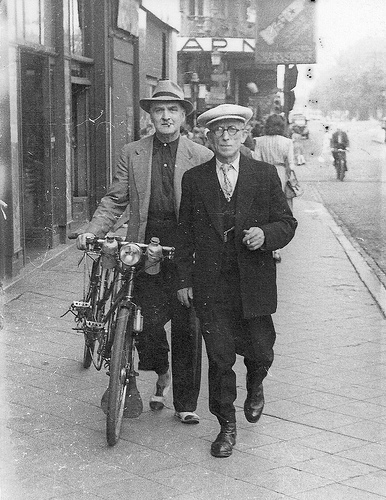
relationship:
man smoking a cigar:
[76, 80, 214, 425] [166, 121, 173, 127]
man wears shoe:
[110, 72, 204, 442] [173, 407, 201, 426]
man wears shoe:
[110, 72, 204, 442] [151, 376, 170, 411]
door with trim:
[15, 46, 53, 264] [15, 42, 57, 270]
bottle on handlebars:
[144, 237, 163, 276] [82, 234, 178, 274]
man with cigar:
[135, 78, 201, 166] [166, 121, 170, 129]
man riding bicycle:
[329, 125, 348, 170] [331, 147, 349, 180]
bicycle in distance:
[331, 147, 349, 180] [0, 15, 373, 290]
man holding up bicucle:
[76, 65, 223, 426] [52, 222, 168, 437]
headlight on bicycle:
[119, 240, 142, 267] [58, 228, 177, 449]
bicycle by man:
[58, 228, 177, 449] [173, 102, 295, 455]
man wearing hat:
[173, 102, 295, 455] [193, 103, 253, 123]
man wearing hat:
[76, 80, 214, 425] [138, 81, 194, 111]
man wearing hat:
[86, 108, 192, 433] [137, 76, 195, 108]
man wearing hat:
[193, 119, 312, 462] [194, 103, 263, 131]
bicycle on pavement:
[58, 228, 177, 449] [0, 194, 384, 495]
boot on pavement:
[212, 413, 237, 457] [25, 182, 379, 497]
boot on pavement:
[246, 373, 267, 417] [25, 182, 379, 497]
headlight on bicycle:
[119, 243, 143, 268] [69, 229, 182, 446]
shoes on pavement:
[176, 409, 199, 422] [0, 194, 384, 495]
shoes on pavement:
[150, 374, 170, 410] [0, 194, 384, 495]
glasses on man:
[198, 120, 250, 143] [173, 102, 295, 455]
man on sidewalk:
[173, 102, 295, 455] [0, 196, 386, 499]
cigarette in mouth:
[164, 121, 172, 125] [158, 120, 174, 127]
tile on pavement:
[331, 380, 383, 404] [294, 336, 380, 493]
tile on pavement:
[290, 450, 382, 483] [294, 336, 380, 493]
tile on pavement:
[316, 353, 384, 375] [294, 336, 380, 493]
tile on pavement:
[291, 387, 356, 411] [294, 336, 380, 493]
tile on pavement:
[339, 417, 383, 443] [294, 336, 380, 493]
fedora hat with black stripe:
[135, 78, 199, 116] [148, 89, 181, 97]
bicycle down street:
[328, 148, 349, 178] [300, 114, 384, 290]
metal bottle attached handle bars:
[141, 236, 167, 276] [66, 227, 177, 272]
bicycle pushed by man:
[58, 228, 177, 449] [76, 65, 223, 426]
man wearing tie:
[176, 108, 339, 389] [209, 148, 280, 203]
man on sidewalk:
[173, 102, 295, 455] [258, 212, 377, 495]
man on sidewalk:
[76, 80, 214, 425] [258, 212, 377, 495]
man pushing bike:
[76, 80, 214, 425] [71, 215, 175, 446]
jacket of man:
[79, 133, 219, 243] [76, 80, 214, 425]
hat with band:
[136, 76, 187, 104] [149, 90, 181, 98]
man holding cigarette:
[173, 102, 295, 455] [244, 233, 255, 249]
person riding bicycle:
[327, 123, 351, 184] [329, 148, 351, 181]